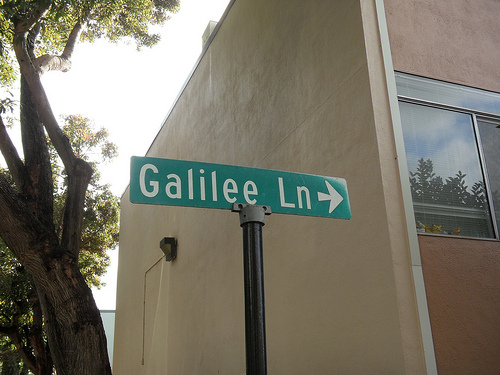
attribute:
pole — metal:
[239, 222, 274, 373]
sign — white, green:
[126, 142, 358, 239]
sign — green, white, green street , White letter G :
[128, 154, 350, 219]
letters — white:
[127, 155, 360, 230]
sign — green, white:
[118, 138, 367, 250]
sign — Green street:
[110, 136, 390, 239]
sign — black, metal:
[136, 133, 348, 233]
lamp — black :
[157, 236, 177, 262]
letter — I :
[195, 160, 209, 205]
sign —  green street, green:
[125, 144, 363, 230]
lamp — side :
[158, 229, 180, 264]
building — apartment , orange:
[113, 0, 499, 373]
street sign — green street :
[149, 144, 353, 240]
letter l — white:
[275, 173, 297, 213]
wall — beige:
[116, 10, 435, 373]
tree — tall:
[2, 2, 178, 373]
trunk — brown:
[41, 285, 110, 373]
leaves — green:
[95, 0, 180, 47]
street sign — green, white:
[128, 155, 350, 222]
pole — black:
[237, 205, 272, 374]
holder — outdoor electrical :
[156, 231, 176, 261]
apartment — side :
[110, 6, 487, 365]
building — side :
[98, 14, 487, 374]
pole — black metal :
[236, 227, 276, 373]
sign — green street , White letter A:
[129, 147, 358, 220]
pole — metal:
[241, 225, 270, 372]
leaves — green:
[4, 114, 118, 291]